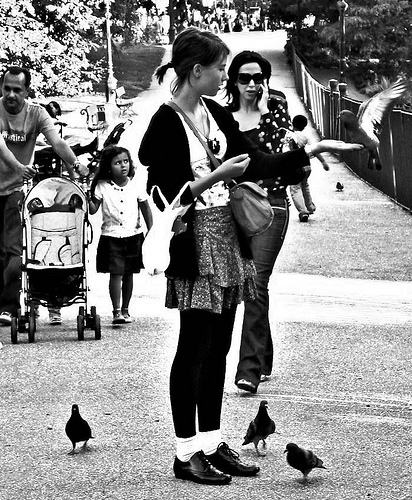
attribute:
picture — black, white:
[2, 5, 411, 497]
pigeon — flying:
[325, 73, 406, 170]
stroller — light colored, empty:
[6, 168, 107, 346]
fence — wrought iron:
[287, 44, 411, 207]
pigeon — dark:
[61, 399, 97, 457]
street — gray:
[12, 342, 400, 491]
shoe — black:
[169, 446, 234, 492]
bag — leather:
[227, 175, 277, 243]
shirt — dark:
[136, 96, 314, 285]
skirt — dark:
[93, 232, 148, 280]